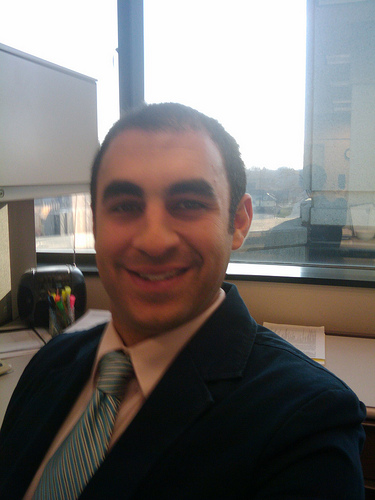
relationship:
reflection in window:
[302, 6, 356, 277] [126, 0, 368, 275]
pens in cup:
[48, 282, 80, 305] [41, 279, 86, 336]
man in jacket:
[3, 87, 374, 496] [0, 280, 367, 500]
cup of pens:
[41, 279, 86, 336] [48, 282, 80, 305]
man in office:
[3, 87, 374, 496] [3, 3, 374, 493]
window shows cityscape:
[126, 0, 368, 275] [42, 193, 102, 241]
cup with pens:
[41, 279, 86, 336] [48, 282, 80, 305]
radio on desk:
[20, 256, 93, 329] [0, 304, 180, 438]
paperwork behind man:
[253, 321, 341, 366] [3, 87, 374, 496]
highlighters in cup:
[48, 281, 79, 306] [41, 279, 86, 336]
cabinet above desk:
[0, 51, 109, 204] [0, 304, 180, 438]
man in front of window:
[3, 87, 374, 496] [126, 0, 368, 275]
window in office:
[126, 0, 368, 275] [3, 3, 374, 493]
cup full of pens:
[41, 279, 86, 336] [48, 282, 80, 305]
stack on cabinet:
[253, 321, 341, 366] [324, 332, 374, 498]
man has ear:
[3, 87, 374, 496] [227, 186, 259, 253]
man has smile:
[3, 87, 374, 496] [115, 255, 199, 293]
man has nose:
[3, 87, 374, 496] [130, 203, 185, 257]